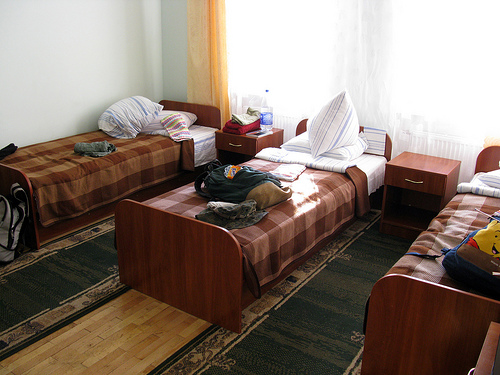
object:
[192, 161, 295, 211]
bag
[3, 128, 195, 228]
blanket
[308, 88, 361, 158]
pillows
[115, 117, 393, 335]
bed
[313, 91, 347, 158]
stripes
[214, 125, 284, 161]
side table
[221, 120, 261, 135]
towel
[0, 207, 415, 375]
floor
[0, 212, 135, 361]
carpet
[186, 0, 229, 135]
curtain